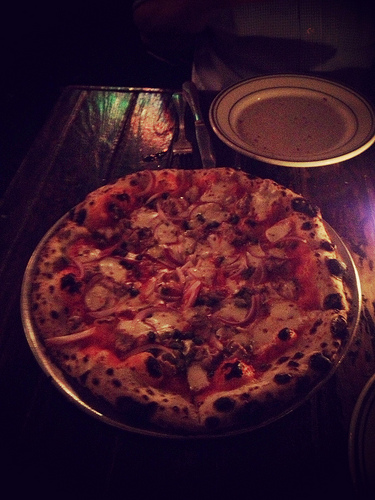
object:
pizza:
[29, 163, 357, 442]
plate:
[209, 68, 375, 168]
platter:
[19, 203, 363, 443]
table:
[1, 77, 375, 500]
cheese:
[80, 292, 128, 311]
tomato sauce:
[82, 325, 115, 353]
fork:
[166, 90, 197, 168]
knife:
[181, 77, 219, 171]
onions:
[241, 247, 267, 325]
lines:
[208, 101, 224, 131]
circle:
[209, 393, 236, 416]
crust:
[194, 339, 336, 428]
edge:
[19, 332, 108, 418]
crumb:
[254, 130, 269, 146]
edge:
[209, 116, 225, 134]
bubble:
[122, 345, 171, 386]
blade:
[194, 124, 214, 172]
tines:
[169, 147, 199, 165]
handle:
[182, 80, 204, 120]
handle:
[170, 93, 189, 128]